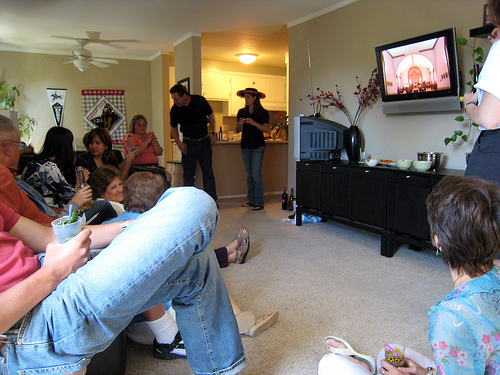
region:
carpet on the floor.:
[325, 278, 367, 306]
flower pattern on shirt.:
[435, 334, 467, 362]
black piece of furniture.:
[350, 188, 412, 218]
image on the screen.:
[390, 50, 437, 82]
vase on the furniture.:
[349, 130, 358, 162]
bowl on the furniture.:
[392, 158, 412, 170]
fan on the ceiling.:
[67, 54, 110, 74]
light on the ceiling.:
[234, 51, 260, 67]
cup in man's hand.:
[51, 218, 81, 242]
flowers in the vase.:
[315, 91, 345, 112]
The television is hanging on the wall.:
[307, 9, 491, 153]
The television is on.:
[301, 11, 489, 152]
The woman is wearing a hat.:
[225, 80, 276, 215]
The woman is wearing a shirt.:
[230, 71, 280, 211]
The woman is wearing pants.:
[226, 80, 271, 220]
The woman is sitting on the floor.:
[302, 170, 497, 371]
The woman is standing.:
[224, 82, 275, 218]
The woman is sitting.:
[120, 108, 175, 193]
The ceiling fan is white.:
[1, 2, 189, 82]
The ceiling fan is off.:
[1, 0, 229, 81]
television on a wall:
[360, 26, 472, 125]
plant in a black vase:
[301, 68, 386, 177]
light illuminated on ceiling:
[224, 46, 266, 71]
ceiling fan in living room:
[44, 40, 136, 82]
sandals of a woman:
[227, 221, 264, 266]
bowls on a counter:
[389, 156, 434, 173]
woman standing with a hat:
[227, 79, 279, 226]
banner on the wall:
[36, 80, 80, 131]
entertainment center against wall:
[291, 158, 430, 254]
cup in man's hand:
[47, 198, 94, 254]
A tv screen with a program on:
[361, 25, 473, 107]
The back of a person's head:
[425, 182, 497, 284]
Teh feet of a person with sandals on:
[215, 222, 258, 269]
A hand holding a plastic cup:
[45, 200, 96, 286]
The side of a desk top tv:
[286, 106, 346, 168]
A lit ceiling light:
[225, 38, 271, 73]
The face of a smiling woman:
[91, 169, 128, 204]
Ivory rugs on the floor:
[299, 251, 377, 323]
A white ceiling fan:
[45, 40, 122, 82]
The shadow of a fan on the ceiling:
[58, 26, 145, 55]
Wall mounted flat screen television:
[372, 25, 466, 116]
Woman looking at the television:
[316, 173, 498, 373]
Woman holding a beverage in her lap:
[315, 173, 496, 373]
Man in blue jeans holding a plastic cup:
[0, 181, 249, 373]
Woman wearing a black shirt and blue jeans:
[232, 86, 272, 213]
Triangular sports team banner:
[45, 86, 70, 127]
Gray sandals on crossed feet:
[229, 223, 252, 265]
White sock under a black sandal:
[145, 308, 187, 357]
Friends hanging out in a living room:
[1, 0, 498, 371]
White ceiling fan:
[48, 37, 117, 74]